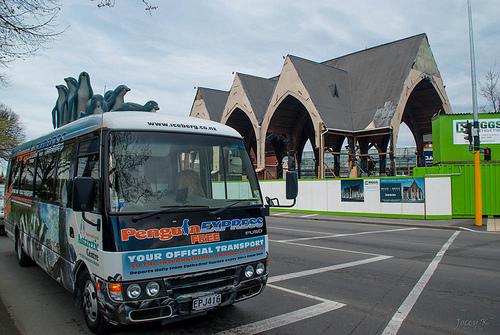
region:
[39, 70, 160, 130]
Fake penguins on a bus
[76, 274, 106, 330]
The front tire of a bus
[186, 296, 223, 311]
The license plate of a bus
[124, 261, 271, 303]
Headlights of a bus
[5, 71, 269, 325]
A tour bus driving down the road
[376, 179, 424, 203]
A sign on the side of the road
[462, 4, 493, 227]
A traffic light pole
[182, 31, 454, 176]
A large steepled building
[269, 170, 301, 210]
A mirror on a bus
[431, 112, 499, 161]
A green storage container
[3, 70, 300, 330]
a colorful bus on the street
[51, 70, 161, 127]
decorative penguins on top of the bus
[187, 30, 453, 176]
a shelter behind the bus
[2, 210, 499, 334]
a paved city street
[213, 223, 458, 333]
white lines in the street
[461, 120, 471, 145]
a traffic signal attached to the pole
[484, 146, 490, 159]
a crossing signal attached to the pole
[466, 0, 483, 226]
a painted metal pole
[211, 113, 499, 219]
a green and white fence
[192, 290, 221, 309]
license plate on the bus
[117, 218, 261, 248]
Penguin Express advertisement on a bus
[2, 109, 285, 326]
Penguin express bus that is parked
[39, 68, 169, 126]
Cluster of penguins on top of penguin express bus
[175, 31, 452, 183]
Chapple style incomplete building in background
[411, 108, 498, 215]
Lime green storage containers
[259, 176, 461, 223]
White and green wooden fence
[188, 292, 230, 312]
EPJ416 licence plate on Penguin Express bus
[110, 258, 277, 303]
Headlights on a penguin express bus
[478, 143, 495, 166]
Cross walk indicator currently red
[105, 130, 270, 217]
Front windshield of a bus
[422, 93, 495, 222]
the containers are green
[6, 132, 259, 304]
the bus is white and blue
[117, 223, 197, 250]
red letters on the bus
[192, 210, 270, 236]
blue letters on the bus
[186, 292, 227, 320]
license plate is white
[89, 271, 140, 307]
the head light is orange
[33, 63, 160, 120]
penguins on top of car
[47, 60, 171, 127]
the penguins are blue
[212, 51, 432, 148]
the roof is brown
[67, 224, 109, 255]
green letters on side of car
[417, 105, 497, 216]
the storage unit is bright green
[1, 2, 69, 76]
the tree is bare of leaves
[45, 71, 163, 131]
penguin figurines are on top of the bus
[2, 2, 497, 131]
the sky is grey and cloudy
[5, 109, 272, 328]
the bus is parked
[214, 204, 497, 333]
the street is grey with white lines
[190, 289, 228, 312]
the license plate is white with black letters and numbers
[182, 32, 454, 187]
the wooden structure is under construction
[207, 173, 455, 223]
the white barrier with green trim is long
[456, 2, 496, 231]
the traffic signals are on a tall pole